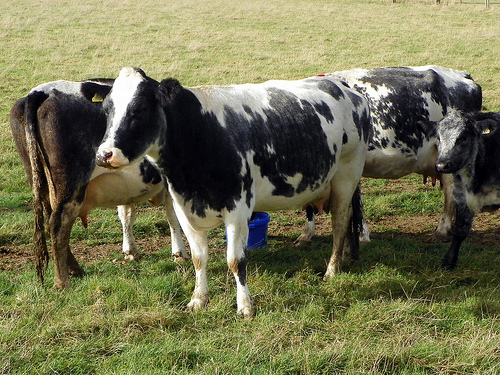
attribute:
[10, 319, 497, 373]
field — grass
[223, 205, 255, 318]
leg —   cow's,  the left,  the front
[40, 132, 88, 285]
leg — back right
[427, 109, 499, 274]
cows — Several 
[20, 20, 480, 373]
green field — green 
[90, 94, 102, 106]
tag — yellow 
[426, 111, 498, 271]
cow — small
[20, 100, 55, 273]
tail —  long ,   cow's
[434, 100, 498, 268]
cow — standing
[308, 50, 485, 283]
cow — standing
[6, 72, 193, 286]
cow — standing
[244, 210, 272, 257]
bucket —  blue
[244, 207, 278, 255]
pail — Blue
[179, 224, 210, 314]
leg —  the right,  the  front,  Cow's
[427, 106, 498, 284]
calf — small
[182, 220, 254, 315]
front legs —   cow's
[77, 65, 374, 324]
cow — standing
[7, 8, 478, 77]
field — grass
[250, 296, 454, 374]
field — grass